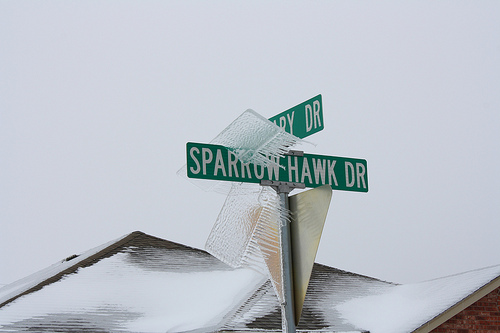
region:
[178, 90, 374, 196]
green signs on top of pole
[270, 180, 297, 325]
a pole color gray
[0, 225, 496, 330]
snow on roof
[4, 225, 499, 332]
roof is color black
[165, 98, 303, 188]
a piece of ice on sign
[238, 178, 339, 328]
a sign in triangle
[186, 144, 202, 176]
letter S on sign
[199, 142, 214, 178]
letter P on sign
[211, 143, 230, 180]
letter A on sign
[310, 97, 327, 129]
letter R on sign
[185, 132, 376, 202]
green sign with white letters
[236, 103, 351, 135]
green sign with white letters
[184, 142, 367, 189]
name of street on sign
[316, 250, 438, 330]
snowy roof of house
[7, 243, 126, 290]
snowy roof of house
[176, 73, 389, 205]
two street signs on post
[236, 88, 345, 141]
a street sign on post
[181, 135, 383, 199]
a street sign on post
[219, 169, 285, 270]
ice formation on sign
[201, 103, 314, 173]
ice formation on sign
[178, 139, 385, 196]
the street sign is green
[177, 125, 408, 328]
street sign attached to a pole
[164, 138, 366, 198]
street sign on pole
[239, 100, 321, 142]
street sign on pole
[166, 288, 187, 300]
patch of snow on roof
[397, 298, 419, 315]
patch of snow on roof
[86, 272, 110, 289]
patch of snow on roof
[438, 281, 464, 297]
patch of snow on roof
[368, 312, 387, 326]
patch of snow on roof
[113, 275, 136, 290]
patch of snow on roof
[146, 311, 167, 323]
patch of snow on roof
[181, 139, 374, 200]
green street sign with white letters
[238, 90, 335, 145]
green street sign with white letters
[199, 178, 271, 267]
sheet of ice on street sign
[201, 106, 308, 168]
sheet of ice on street sign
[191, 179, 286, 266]
melting ice on street sign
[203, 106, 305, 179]
melting ice on street sign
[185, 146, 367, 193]
white letters on street sign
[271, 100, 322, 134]
white letters on street sign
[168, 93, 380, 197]
street sign at intersection of two roads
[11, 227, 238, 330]
snow covered roof top